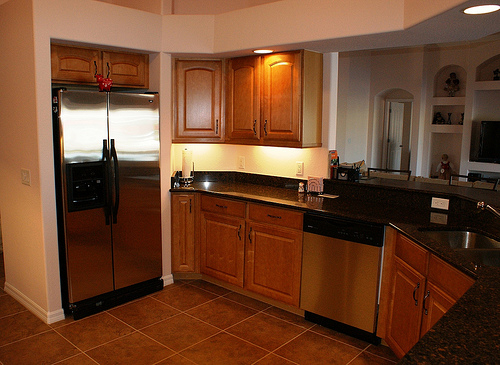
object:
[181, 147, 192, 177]
candle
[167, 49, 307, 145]
cabinets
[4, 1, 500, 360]
kitchen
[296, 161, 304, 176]
power outlet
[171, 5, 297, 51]
wall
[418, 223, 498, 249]
sink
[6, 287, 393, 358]
floor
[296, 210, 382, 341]
dishwasher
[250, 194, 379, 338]
cabinet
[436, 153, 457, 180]
doll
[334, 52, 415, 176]
wall shelf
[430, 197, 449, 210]
power outlet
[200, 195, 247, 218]
drawer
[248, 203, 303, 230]
drawer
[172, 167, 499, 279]
counter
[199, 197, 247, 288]
cabinet door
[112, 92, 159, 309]
door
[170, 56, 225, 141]
cabinets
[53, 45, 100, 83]
cabinet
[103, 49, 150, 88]
cabinet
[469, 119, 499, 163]
entertainment center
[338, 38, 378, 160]
wall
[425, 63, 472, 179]
shelves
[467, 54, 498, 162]
shelves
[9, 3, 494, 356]
scene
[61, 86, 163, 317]
freezer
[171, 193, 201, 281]
cabinets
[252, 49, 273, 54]
light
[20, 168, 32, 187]
light switch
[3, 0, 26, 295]
wall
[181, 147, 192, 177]
roll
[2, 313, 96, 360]
tiles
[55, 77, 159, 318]
doors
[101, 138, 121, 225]
handles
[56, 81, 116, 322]
door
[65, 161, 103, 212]
water maker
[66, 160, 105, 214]
ice maker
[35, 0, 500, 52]
ceiling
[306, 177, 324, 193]
napkins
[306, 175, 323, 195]
holder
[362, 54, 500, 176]
wall shelf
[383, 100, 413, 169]
door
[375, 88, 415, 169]
archway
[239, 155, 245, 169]
outlet